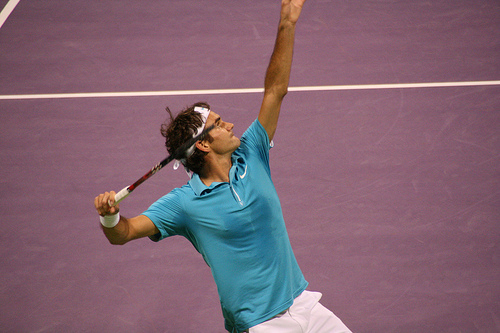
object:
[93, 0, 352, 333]
man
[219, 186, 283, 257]
sweat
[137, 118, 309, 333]
shirt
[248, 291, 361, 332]
shorts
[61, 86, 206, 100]
line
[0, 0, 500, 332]
court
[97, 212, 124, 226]
wristband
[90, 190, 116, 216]
hand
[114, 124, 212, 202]
racket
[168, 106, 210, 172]
headband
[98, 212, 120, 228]
band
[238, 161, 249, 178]
logo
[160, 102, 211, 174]
hair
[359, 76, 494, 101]
stripe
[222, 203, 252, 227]
stains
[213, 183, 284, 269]
cloth